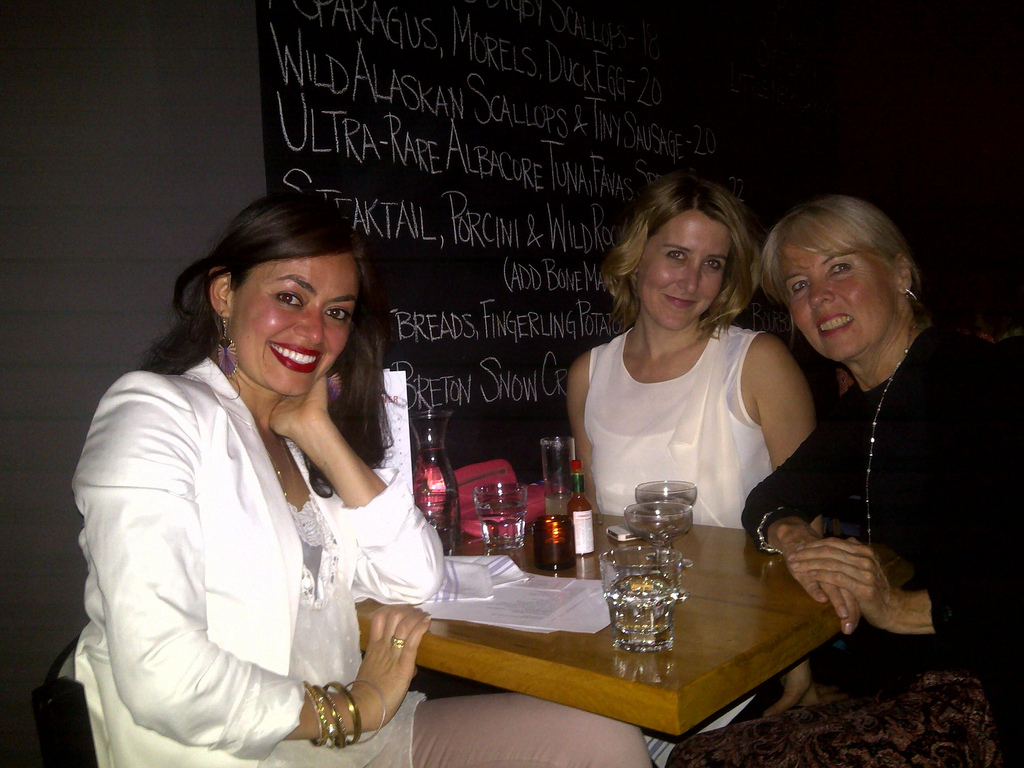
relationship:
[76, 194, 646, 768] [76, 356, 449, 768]
woman wears white jacket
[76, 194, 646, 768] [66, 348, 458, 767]
woman wears white jacket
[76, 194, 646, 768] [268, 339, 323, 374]
woman wears lips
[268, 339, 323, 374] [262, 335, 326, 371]
lips on lips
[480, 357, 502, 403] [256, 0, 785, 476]
letter on sign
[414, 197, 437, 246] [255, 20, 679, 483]
letter on sign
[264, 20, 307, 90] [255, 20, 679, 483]
letter on sign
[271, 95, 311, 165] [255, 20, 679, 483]
letter on sign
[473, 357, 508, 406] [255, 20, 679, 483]
letter on sign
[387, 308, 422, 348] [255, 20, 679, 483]
letter on sign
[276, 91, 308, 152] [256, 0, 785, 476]
letter on sign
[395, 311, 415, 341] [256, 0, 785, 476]
letter on sign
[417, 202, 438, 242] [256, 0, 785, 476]
letter on sign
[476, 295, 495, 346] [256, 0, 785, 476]
letter on sign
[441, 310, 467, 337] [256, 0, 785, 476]
letter on sign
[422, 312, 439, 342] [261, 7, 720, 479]
letter on sign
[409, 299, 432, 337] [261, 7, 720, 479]
letter on sign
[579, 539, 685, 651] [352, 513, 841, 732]
glass on table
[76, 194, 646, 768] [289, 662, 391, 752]
woman wearing bracelets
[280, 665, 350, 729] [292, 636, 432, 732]
bracelet on wrist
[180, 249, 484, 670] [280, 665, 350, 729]
woman wearing bracelet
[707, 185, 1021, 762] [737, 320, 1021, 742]
woman wearing sweater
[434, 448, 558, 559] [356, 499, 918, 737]
purse on table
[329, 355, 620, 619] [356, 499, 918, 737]
clear vase on table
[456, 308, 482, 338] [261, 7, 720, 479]
letter on sign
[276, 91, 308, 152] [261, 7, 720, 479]
letter on sign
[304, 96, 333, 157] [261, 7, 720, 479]
letter on sign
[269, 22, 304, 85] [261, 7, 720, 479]
letter on sign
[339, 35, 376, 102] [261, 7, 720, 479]
letter on sign